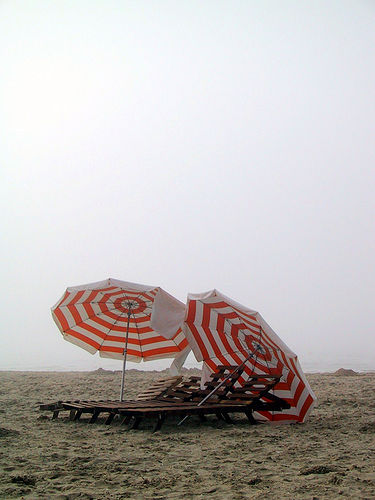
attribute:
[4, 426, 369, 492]
sand — light tan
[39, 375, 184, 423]
chair — wooden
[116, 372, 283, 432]
chair — leaning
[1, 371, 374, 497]
beach — large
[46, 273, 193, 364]
umbrella — striped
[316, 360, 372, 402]
mound — dirt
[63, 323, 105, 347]
stripes — red, white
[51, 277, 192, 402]
umbrella — striped, leaning, white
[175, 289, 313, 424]
umbrella — unsupported, lying, large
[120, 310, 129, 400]
pole — silver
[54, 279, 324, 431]
stripes — red, white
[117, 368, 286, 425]
chair — brown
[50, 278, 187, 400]
beach umbrella — orange, white, striped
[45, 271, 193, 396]
umbrella — striped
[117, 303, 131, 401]
umbrella post — on, attached to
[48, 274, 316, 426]
umbrellas — large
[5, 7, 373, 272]
sky — hazy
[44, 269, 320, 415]
umbrellas — red, white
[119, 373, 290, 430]
bench — brown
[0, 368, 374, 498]
sand — dark grey, trampled, brown, clumpy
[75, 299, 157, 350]
umbrella — white, red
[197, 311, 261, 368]
umbrella — white, red